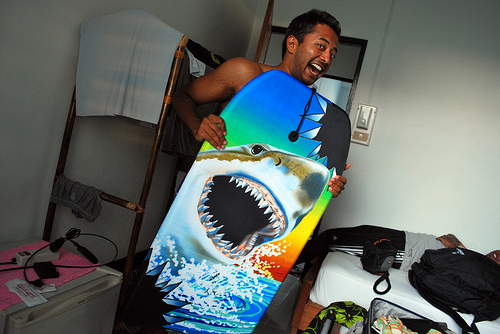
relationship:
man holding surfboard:
[172, 9, 350, 199] [119, 69, 350, 332]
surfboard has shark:
[119, 69, 350, 332] [158, 142, 331, 267]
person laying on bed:
[303, 224, 500, 270] [291, 247, 498, 333]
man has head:
[172, 9, 350, 199] [284, 9, 340, 84]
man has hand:
[172, 9, 350, 199] [197, 113, 228, 150]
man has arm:
[172, 9, 350, 199] [173, 56, 242, 127]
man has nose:
[172, 9, 350, 199] [323, 49, 330, 61]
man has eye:
[172, 9, 350, 199] [316, 43, 326, 52]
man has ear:
[172, 9, 350, 199] [286, 36, 297, 55]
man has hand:
[172, 9, 350, 199] [330, 176, 348, 199]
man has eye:
[172, 9, 350, 199] [332, 53, 337, 59]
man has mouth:
[172, 9, 350, 199] [307, 63, 324, 78]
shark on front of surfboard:
[158, 142, 331, 267] [119, 69, 350, 332]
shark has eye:
[158, 142, 331, 267] [250, 146, 261, 154]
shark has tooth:
[158, 142, 331, 267] [251, 188, 256, 194]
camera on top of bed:
[362, 236, 395, 274] [291, 247, 498, 333]